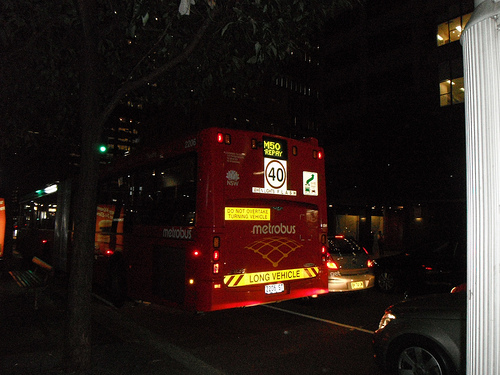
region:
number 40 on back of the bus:
[260, 159, 287, 191]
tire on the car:
[379, 333, 445, 373]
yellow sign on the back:
[214, 263, 328, 280]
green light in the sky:
[90, 132, 113, 162]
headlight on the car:
[327, 250, 337, 270]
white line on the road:
[300, 303, 342, 332]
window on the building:
[431, 76, 466, 113]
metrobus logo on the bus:
[240, 223, 297, 236]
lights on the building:
[367, 199, 425, 221]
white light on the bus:
[38, 183, 59, 193]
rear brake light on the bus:
[213, 252, 220, 263]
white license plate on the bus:
[264, 283, 286, 294]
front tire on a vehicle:
[395, 343, 450, 373]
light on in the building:
[437, 79, 464, 107]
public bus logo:
[251, 223, 298, 236]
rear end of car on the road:
[325, 239, 375, 291]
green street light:
[99, 145, 106, 151]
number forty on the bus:
[262, 159, 288, 186]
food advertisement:
[95, 204, 125, 246]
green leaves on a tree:
[133, 0, 307, 73]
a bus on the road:
[20, 105, 349, 331]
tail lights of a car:
[325, 245, 375, 275]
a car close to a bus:
[195, 127, 380, 297]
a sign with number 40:
[251, 131, 296, 196]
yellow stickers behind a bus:
[215, 196, 321, 291]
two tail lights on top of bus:
[200, 125, 330, 172]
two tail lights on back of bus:
[206, 244, 330, 265]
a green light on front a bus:
[33, 183, 46, 204]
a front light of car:
[366, 303, 402, 343]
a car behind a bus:
[164, 135, 473, 366]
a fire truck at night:
[39, 46, 401, 336]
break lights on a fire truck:
[189, 124, 359, 334]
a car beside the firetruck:
[311, 214, 392, 306]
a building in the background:
[54, 13, 354, 135]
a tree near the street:
[34, 101, 138, 357]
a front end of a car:
[357, 292, 482, 373]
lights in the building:
[414, 17, 474, 116]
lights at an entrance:
[333, 187, 439, 244]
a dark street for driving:
[94, 269, 373, 361]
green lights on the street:
[22, 141, 134, 217]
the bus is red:
[88, 115, 333, 340]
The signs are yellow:
[222, 265, 326, 288]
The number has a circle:
[261, 160, 291, 194]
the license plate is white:
[263, 283, 289, 295]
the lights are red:
[191, 246, 226, 263]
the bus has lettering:
[224, 139, 319, 284]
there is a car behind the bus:
[373, 286, 466, 373]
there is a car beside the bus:
[330, 233, 383, 295]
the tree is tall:
[61, 38, 198, 373]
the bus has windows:
[106, 154, 198, 223]